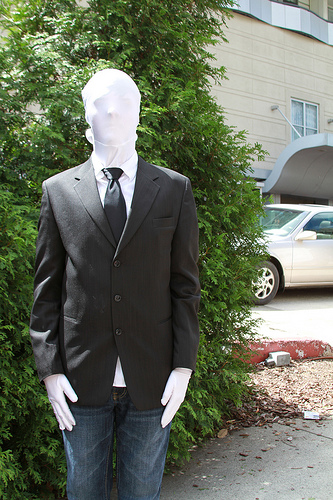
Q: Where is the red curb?
A: Behind the brown gravel.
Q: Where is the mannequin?
A: In front of tall green tree.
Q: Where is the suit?
A: On a mannequin.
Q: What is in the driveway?
A: A car.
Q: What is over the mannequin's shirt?
A: A jacket.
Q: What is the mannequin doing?
A: Standing in a suit.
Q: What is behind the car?
A: A driveway.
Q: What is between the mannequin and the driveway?
A: Gravel.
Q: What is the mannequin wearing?
A: A coat.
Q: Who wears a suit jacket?
A: A man.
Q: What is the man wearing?
A: Blue jeans.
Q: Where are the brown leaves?
A: On the ground.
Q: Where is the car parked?
A: In the driveway.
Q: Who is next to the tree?
A: The man.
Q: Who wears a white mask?
A: The man.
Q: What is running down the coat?
A: Buttons.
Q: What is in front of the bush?
A: Mannequin.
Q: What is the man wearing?
A: Blue jeans.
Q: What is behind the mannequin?
A: Bush.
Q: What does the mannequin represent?
A: A man.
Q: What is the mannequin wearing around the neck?
A: A tie.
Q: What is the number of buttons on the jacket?
A: Three.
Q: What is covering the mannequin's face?
A: White cloth.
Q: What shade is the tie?
A: Black.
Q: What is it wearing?
A: A tuxedo.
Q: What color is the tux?
A: Black.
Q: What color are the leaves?
A: Green.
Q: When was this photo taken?
A: During the day.